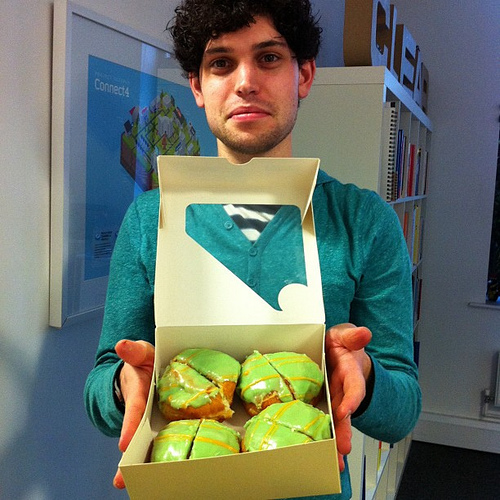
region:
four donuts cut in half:
[114, 325, 358, 487]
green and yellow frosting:
[161, 347, 245, 419]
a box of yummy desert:
[141, 216, 364, 498]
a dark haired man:
[148, 0, 347, 158]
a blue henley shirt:
[30, 165, 481, 457]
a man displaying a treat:
[80, 2, 453, 467]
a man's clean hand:
[314, 307, 376, 480]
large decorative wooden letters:
[353, 0, 453, 137]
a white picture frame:
[38, 6, 225, 347]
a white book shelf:
[330, 55, 482, 463]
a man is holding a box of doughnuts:
[97, 6, 425, 473]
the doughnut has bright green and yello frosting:
[118, 317, 347, 493]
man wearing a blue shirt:
[94, 3, 406, 483]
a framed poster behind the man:
[51, 3, 196, 330]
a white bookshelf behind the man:
[326, 71, 443, 161]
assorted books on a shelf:
[394, 122, 431, 199]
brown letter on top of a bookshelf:
[349, 2, 434, 60]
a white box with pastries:
[114, 149, 348, 488]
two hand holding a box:
[99, 317, 396, 494]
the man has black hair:
[81, 9, 380, 497]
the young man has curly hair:
[161, 2, 319, 74]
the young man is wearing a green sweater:
[91, 177, 404, 439]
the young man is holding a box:
[119, 149, 342, 497]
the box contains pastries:
[114, 155, 346, 496]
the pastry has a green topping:
[160, 347, 240, 422]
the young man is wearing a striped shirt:
[222, 201, 275, 245]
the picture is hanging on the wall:
[49, 2, 243, 328]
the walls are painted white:
[2, 5, 488, 497]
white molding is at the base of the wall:
[405, 407, 498, 454]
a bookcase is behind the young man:
[238, 63, 431, 498]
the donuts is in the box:
[134, 313, 401, 447]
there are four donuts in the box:
[151, 342, 303, 497]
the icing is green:
[162, 343, 304, 480]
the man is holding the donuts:
[107, 55, 342, 478]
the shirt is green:
[112, 174, 467, 433]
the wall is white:
[442, 33, 485, 216]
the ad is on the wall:
[39, 8, 151, 362]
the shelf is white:
[336, 67, 443, 482]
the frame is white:
[39, 12, 230, 352]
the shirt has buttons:
[221, 212, 287, 314]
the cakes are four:
[150, 338, 348, 465]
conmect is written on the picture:
[82, 62, 172, 123]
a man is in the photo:
[123, 4, 413, 497]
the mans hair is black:
[128, 3, 343, 152]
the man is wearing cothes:
[108, 95, 442, 465]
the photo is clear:
[1, 3, 487, 489]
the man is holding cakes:
[96, 297, 366, 498]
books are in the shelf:
[377, 82, 438, 340]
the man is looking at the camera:
[159, 0, 359, 270]